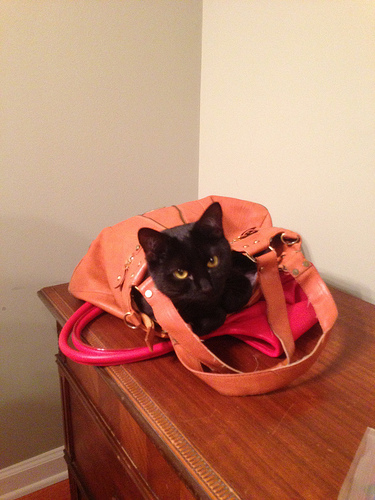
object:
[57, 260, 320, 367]
purse